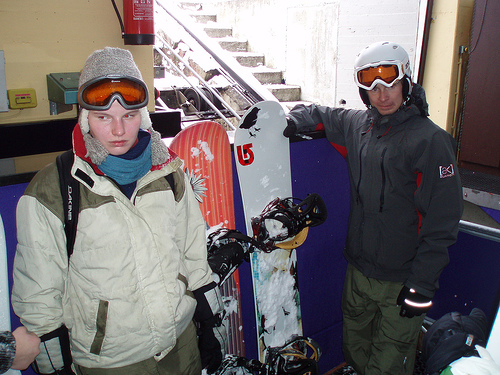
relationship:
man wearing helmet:
[284, 35, 470, 374] [350, 35, 417, 114]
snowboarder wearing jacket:
[284, 35, 470, 374] [286, 98, 480, 301]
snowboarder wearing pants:
[284, 35, 470, 374] [341, 256, 428, 374]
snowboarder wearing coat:
[4, 42, 231, 374] [6, 109, 227, 374]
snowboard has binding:
[232, 88, 317, 374] [247, 190, 329, 260]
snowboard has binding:
[232, 88, 317, 374] [265, 333, 322, 374]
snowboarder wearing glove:
[4, 42, 231, 374] [192, 321, 225, 374]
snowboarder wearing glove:
[284, 35, 470, 374] [392, 279, 432, 320]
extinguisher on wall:
[118, 1, 155, 52] [1, 0, 164, 117]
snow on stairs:
[264, 81, 298, 89] [175, 0, 318, 110]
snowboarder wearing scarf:
[4, 42, 231, 374] [87, 132, 164, 187]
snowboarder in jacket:
[284, 35, 470, 374] [286, 98, 480, 301]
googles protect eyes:
[73, 74, 151, 114] [91, 107, 139, 127]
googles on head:
[73, 74, 151, 114] [62, 43, 161, 159]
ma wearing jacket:
[284, 35, 470, 374] [286, 98, 480, 301]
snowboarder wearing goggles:
[4, 42, 231, 374] [73, 74, 151, 114]